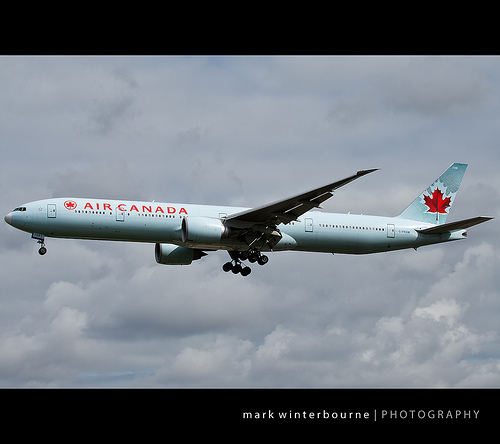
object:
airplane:
[3, 162, 497, 276]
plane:
[7, 162, 493, 273]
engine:
[181, 216, 244, 245]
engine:
[154, 243, 209, 266]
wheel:
[37, 246, 48, 256]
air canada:
[83, 202, 189, 215]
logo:
[420, 178, 456, 221]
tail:
[393, 163, 494, 252]